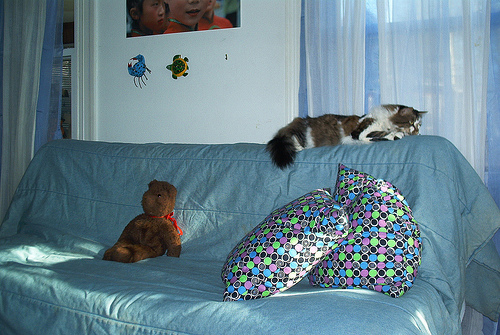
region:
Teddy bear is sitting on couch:
[92, 173, 179, 267]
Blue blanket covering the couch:
[3, 130, 481, 332]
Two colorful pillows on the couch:
[230, 162, 412, 307]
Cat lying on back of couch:
[266, 97, 428, 174]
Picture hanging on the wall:
[114, 0, 253, 47]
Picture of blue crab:
[111, 51, 154, 80]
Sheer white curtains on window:
[286, 1, 491, 178]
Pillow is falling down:
[206, 172, 351, 286]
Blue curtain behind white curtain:
[2, 3, 77, 142]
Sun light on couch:
[406, 292, 438, 333]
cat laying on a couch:
[270, 98, 425, 165]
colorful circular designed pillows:
[239, 167, 416, 292]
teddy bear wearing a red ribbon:
[100, 180, 182, 267]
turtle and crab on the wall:
[123, 51, 190, 84]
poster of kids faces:
[126, 0, 246, 42]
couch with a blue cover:
[11, 125, 493, 334]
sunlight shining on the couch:
[9, 231, 101, 319]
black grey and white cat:
[277, 101, 419, 156]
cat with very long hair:
[267, 99, 421, 156]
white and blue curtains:
[294, 7, 492, 162]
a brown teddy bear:
[107, 180, 187, 261]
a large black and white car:
[266, 98, 430, 177]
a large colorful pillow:
[308, 154, 420, 297]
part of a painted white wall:
[111, 92, 276, 139]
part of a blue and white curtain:
[295, 0, 499, 187]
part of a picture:
[123, 0, 244, 40]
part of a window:
[43, 47, 77, 137]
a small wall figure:
[165, 53, 194, 81]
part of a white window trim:
[74, 0, 102, 144]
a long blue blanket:
[1, 133, 498, 333]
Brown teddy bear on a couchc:
[98, 178, 187, 265]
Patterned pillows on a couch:
[222, 164, 423, 302]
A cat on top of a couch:
[270, 100, 429, 166]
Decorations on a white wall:
[126, 52, 190, 87]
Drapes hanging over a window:
[303, 5, 498, 137]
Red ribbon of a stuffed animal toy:
[147, 210, 184, 233]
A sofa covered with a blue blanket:
[8, 137, 487, 333]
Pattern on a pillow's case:
[256, 230, 298, 273]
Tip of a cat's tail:
[268, 145, 296, 170]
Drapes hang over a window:
[2, 4, 64, 219]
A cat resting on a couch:
[261, 92, 432, 173]